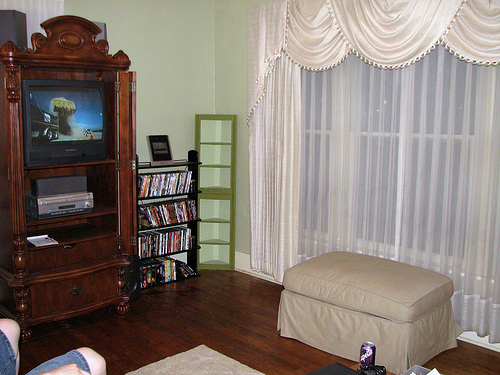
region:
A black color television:
[19, 76, 111, 168]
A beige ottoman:
[274, 247, 460, 372]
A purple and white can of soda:
[356, 341, 378, 368]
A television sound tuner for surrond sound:
[27, 190, 99, 221]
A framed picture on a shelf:
[141, 132, 176, 168]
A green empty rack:
[191, 108, 238, 274]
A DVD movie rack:
[128, 147, 203, 290]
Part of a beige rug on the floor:
[120, 341, 267, 373]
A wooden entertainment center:
[0, 12, 142, 324]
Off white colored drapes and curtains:
[248, 1, 498, 355]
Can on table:
[355, 336, 381, 370]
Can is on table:
[357, 340, 377, 369]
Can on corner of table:
[357, 338, 379, 371]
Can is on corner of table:
[357, 340, 377, 372]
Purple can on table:
[359, 337, 375, 372]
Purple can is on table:
[357, 336, 379, 372]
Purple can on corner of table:
[354, 337, 380, 369]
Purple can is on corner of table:
[357, 337, 379, 374]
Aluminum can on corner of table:
[355, 338, 378, 370]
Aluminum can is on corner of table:
[356, 337, 378, 373]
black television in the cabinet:
[20, 79, 110, 161]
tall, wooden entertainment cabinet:
[0, 15, 134, 339]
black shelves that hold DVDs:
[134, 150, 201, 289]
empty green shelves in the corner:
[194, 111, 236, 268]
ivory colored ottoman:
[276, 250, 461, 371]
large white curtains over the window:
[245, 0, 498, 349]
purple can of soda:
[360, 341, 375, 369]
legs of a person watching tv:
[0, 318, 105, 373]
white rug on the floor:
[115, 343, 269, 373]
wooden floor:
[1, 269, 496, 371]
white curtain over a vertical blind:
[247, 0, 496, 284]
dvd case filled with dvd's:
[132, 163, 200, 286]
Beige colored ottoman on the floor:
[269, 240, 490, 368]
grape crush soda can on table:
[360, 343, 376, 364]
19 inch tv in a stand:
[20, 82, 114, 159]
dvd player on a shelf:
[40, 190, 107, 217]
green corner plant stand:
[199, 115, 240, 272]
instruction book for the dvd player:
[30, 233, 62, 248]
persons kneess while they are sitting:
[0, 315, 115, 372]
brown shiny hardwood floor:
[163, 294, 243, 334]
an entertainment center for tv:
[0, 14, 138, 341]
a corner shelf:
[198, 113, 235, 273]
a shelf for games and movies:
[133, 145, 197, 292]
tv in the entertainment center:
[19, 78, 114, 168]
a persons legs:
[3, 318, 111, 374]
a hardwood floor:
[1, 262, 497, 372]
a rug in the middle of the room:
[120, 343, 271, 372]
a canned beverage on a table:
[360, 340, 376, 373]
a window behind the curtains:
[247, 3, 497, 345]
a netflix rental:
[27, 232, 58, 249]